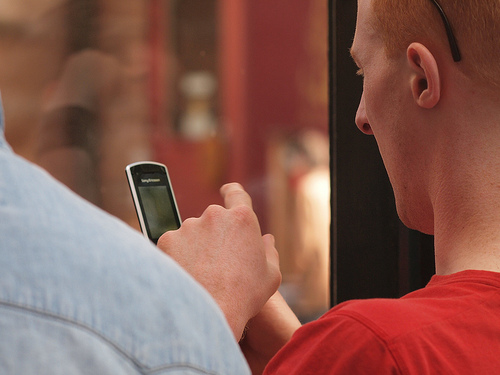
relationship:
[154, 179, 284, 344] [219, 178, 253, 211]
hand has finger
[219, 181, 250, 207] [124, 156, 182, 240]
finger by phone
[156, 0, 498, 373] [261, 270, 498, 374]
man in shirt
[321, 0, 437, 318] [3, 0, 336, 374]
black border on window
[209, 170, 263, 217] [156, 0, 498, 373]
finger of man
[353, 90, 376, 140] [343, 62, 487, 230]
nose of face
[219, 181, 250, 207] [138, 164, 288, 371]
finger of hand